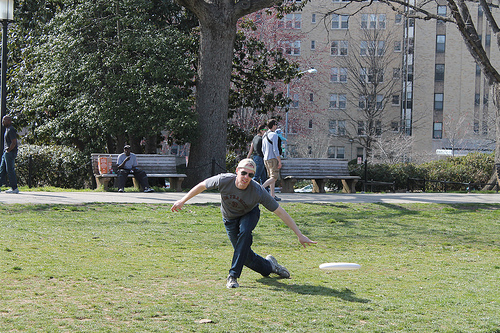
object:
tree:
[170, 0, 281, 194]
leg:
[228, 205, 259, 278]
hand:
[297, 234, 319, 249]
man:
[116, 144, 156, 193]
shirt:
[203, 173, 279, 223]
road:
[0, 189, 500, 205]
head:
[234, 157, 257, 186]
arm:
[260, 187, 303, 239]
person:
[168, 157, 320, 289]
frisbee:
[317, 262, 361, 270]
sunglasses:
[237, 170, 255, 180]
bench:
[90, 153, 188, 192]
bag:
[97, 154, 112, 175]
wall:
[411, 0, 434, 161]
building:
[161, 0, 500, 167]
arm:
[179, 172, 223, 201]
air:
[377, 223, 454, 242]